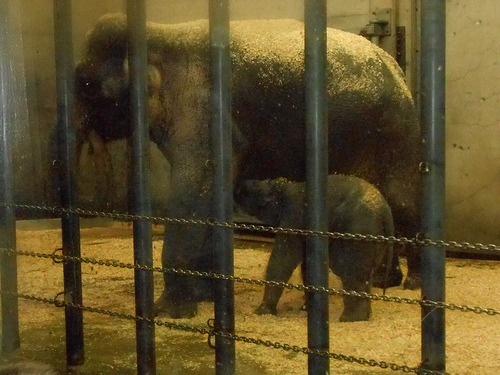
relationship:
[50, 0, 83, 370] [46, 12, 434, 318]
bar on adult elephant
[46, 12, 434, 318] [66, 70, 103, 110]
adult elephant has eye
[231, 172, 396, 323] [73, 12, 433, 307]
baby standing with adult elephant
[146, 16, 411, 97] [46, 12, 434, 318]
dirt on adult elephant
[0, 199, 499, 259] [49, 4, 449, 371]
chain crossing bars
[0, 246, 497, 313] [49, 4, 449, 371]
chain crossing bars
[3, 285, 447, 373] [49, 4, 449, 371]
chain crossing bars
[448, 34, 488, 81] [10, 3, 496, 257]
crack in wall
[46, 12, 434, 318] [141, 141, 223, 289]
adult elephant has leg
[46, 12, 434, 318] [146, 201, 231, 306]
adult elephant has leg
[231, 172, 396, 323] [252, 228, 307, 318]
baby has leg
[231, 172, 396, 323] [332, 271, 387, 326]
baby has leg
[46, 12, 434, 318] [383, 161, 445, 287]
adult elephant has leg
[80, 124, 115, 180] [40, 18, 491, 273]
tusk on elephant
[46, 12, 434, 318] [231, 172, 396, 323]
adult elephant feeding baby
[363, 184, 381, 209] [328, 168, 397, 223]
hay on back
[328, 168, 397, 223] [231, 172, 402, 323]
back on baby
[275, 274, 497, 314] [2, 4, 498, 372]
chain in front of pen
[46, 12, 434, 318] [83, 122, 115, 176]
adult elephant with tusk